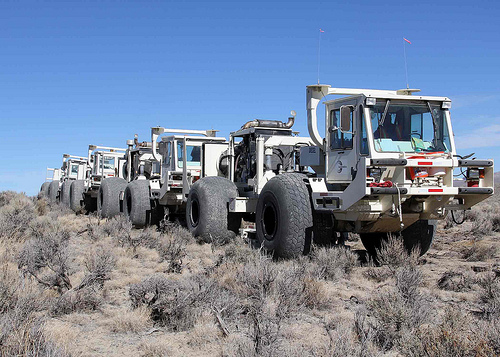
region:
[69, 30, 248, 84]
medium blue sky without clouds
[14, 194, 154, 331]
dry scrub brush on the ground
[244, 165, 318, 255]
large tire on the big vehicle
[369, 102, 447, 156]
front windshield on the truck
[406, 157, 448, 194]
red reflectors on the front of the truck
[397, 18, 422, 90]
flag on top of the truck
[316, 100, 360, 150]
side mirror on the truck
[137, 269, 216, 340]
dead shrubs on the ground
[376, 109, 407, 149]
person driving in the truck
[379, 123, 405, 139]
orange vest on the driver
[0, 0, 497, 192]
Bright clear blue sky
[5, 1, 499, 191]
A bright sunny sky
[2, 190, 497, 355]
A dry arid dessert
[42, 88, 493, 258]
A large convoy of heavy duty vehicles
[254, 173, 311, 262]
A very large black tire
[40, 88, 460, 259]
A large line of white vehicles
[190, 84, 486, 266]
A large white industrial vehicle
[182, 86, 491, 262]
Heavy duty machinee in a dessrt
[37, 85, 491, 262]
A long line of white heavy duty machinery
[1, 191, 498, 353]
A large dessert filled with sagebrush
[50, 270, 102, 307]
Small dead plants in the grass.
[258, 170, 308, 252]
Big black tire on truck.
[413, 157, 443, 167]
Orange light in front of car.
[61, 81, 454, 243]
Group of trucks driving across dirt.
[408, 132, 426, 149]
Small pamphlet of papers in the window.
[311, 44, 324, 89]
Small antenna coming from truck.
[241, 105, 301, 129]
A silver pipe on top of truck.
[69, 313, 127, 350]
Patch of dead grass and dirt.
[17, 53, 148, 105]
Calm blue skies above cars.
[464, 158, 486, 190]
Small red fire extinguisher outside of truck.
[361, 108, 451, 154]
The front window of the first truck.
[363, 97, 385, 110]
The left top headlight of the first truck.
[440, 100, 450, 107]
The top right headlight of the first truck.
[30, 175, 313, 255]
The left tires on the trucks.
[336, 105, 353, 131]
The left side view mirror on the first truck.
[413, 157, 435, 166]
The red reflector on the top bar on the front of the truck.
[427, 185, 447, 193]
The bottom red reflector on the front of the truck.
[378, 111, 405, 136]
The man inside of the truck.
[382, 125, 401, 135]
The orange vest the man is wearing inside of the truck.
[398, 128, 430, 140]
The steering wheel inside of the truck.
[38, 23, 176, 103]
blue sky in the photo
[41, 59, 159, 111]
sky with no clouds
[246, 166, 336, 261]
tire on the vehicle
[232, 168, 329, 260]
black tire on vehicle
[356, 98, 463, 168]
window on the vehicle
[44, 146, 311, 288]
many black tires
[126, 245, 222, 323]
ground next to the vehicles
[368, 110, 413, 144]
person in the truck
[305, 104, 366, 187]
door of the truck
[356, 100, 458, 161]
front window of the truck